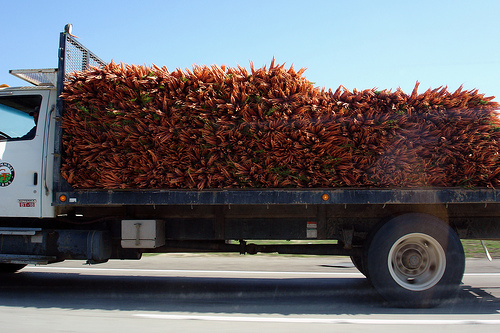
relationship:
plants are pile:
[65, 65, 495, 186] [65, 64, 499, 194]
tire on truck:
[347, 217, 497, 309] [2, 16, 499, 319]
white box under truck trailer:
[115, 215, 161, 254] [58, 47, 498, 226]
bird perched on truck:
[62, 21, 76, 38] [2, 16, 499, 319]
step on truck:
[2, 252, 64, 264] [2, 16, 499, 319]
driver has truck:
[12, 109, 44, 139] [2, 16, 499, 319]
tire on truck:
[347, 217, 497, 309] [0, 40, 492, 321]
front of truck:
[0, 76, 61, 277] [0, 40, 492, 321]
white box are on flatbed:
[115, 215, 161, 254] [52, 190, 499, 210]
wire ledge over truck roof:
[7, 67, 57, 84] [1, 85, 56, 94]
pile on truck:
[65, 64, 499, 194] [2, 16, 499, 319]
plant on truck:
[136, 77, 143, 82] [2, 16, 499, 319]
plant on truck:
[191, 94, 203, 104] [2, 16, 499, 319]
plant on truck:
[256, 77, 268, 87] [2, 16, 499, 319]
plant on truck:
[350, 118, 358, 123] [2, 16, 499, 319]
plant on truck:
[398, 96, 403, 102] [2, 16, 499, 319]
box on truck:
[118, 213, 162, 258] [2, 16, 499, 319]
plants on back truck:
[65, 65, 495, 186] [5, 42, 64, 249]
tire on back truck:
[347, 217, 497, 309] [2, 16, 499, 319]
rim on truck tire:
[389, 232, 441, 287] [393, 212, 454, 234]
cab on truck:
[1, 133, 48, 208] [2, 16, 499, 319]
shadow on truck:
[6, 267, 496, 320] [1, 33, 498, 301]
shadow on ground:
[6, 267, 496, 320] [5, 251, 492, 328]